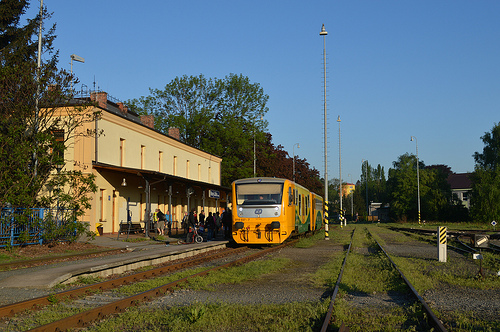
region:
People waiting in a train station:
[176, 205, 218, 240]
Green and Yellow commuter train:
[224, 165, 323, 257]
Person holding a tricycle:
[180, 210, 210, 245]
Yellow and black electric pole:
[315, 25, 335, 249]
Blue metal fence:
[3, 201, 85, 246]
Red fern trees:
[248, 142, 325, 174]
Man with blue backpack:
[158, 211, 172, 230]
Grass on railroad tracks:
[333, 226, 409, 321]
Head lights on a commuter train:
[233, 202, 280, 218]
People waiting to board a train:
[177, 194, 224, 236]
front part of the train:
[223, 151, 313, 268]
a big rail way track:
[332, 205, 434, 315]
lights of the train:
[232, 217, 254, 233]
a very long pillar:
[308, 14, 358, 260]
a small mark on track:
[433, 221, 463, 288]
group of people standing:
[151, 195, 255, 260]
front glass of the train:
[236, 178, 288, 221]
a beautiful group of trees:
[129, 64, 498, 226]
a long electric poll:
[37, 8, 49, 287]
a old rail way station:
[46, 98, 250, 257]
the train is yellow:
[174, 91, 374, 326]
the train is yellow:
[191, 130, 305, 307]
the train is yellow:
[156, 72, 286, 293]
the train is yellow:
[206, 166, 342, 326]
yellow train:
[198, 174, 348, 282]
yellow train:
[224, 185, 324, 262]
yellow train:
[217, 87, 312, 251]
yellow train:
[227, 168, 288, 249]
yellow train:
[172, 130, 272, 264]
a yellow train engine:
[220, 176, 312, 250]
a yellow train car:
[308, 193, 325, 228]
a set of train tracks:
[0, 226, 303, 326]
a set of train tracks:
[317, 216, 442, 330]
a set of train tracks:
[388, 217, 498, 264]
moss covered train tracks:
[319, 217, 422, 290]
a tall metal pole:
[315, 20, 335, 242]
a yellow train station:
[38, 93, 223, 239]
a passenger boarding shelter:
[96, 153, 230, 220]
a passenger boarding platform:
[97, 223, 254, 250]